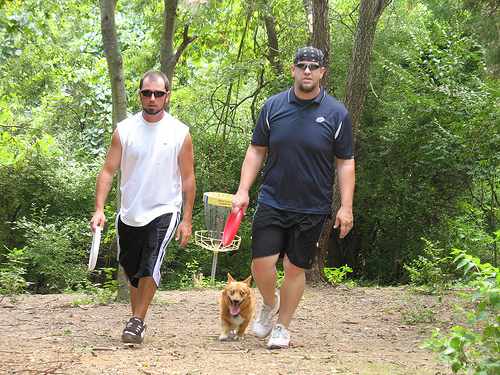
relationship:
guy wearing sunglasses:
[88, 69, 195, 345] [136, 85, 171, 97]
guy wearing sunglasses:
[229, 48, 358, 347] [291, 61, 327, 74]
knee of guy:
[282, 255, 310, 274] [229, 47, 363, 351]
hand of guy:
[332, 205, 352, 235] [229, 47, 363, 351]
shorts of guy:
[252, 204, 325, 269] [229, 47, 363, 351]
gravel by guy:
[1, 287, 458, 372] [229, 47, 363, 351]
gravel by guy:
[1, 287, 458, 372] [88, 69, 195, 345]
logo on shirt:
[317, 116, 328, 124] [250, 88, 345, 213]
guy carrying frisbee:
[229, 48, 358, 347] [182, 165, 280, 245]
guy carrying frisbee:
[88, 69, 195, 345] [83, 216, 107, 278]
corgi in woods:
[217, 272, 253, 340] [369, 35, 475, 184]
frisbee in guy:
[86, 225, 103, 276] [88, 69, 195, 345]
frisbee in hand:
[86, 225, 103, 276] [88, 208, 108, 233]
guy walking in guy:
[88, 69, 195, 345] [229, 48, 358, 347]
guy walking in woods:
[88, 69, 195, 345] [0, 0, 500, 290]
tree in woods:
[307, 0, 393, 286] [370, 109, 496, 290]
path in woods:
[14, 282, 463, 362] [26, 31, 470, 361]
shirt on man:
[257, 93, 360, 226] [256, 30, 323, 363]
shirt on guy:
[102, 109, 192, 223] [88, 69, 195, 345]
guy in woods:
[88, 69, 195, 345] [2, 5, 497, 221]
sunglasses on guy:
[140, 90, 165, 96] [88, 69, 195, 345]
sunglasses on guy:
[293, 63, 321, 68] [229, 48, 358, 347]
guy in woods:
[88, 69, 195, 345] [0, 0, 500, 290]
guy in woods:
[229, 48, 358, 347] [0, 0, 500, 290]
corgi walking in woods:
[201, 272, 253, 314] [25, 88, 486, 353]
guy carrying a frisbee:
[88, 69, 195, 345] [217, 205, 242, 247]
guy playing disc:
[229, 48, 358, 347] [221, 200, 246, 244]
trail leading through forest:
[2, 285, 497, 374] [0, 2, 496, 279]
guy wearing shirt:
[88, 69, 195, 345] [102, 109, 209, 223]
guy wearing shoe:
[229, 48, 358, 347] [267, 326, 290, 349]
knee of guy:
[244, 255, 301, 302] [229, 47, 363, 351]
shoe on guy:
[120, 315, 150, 347] [88, 69, 195, 345]